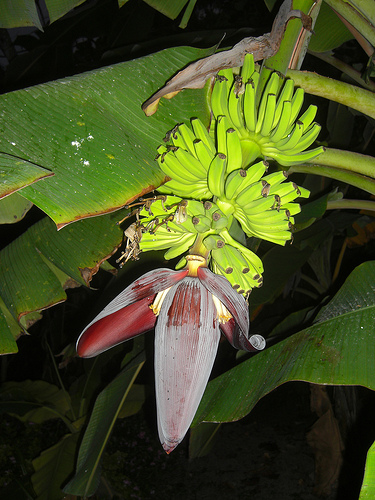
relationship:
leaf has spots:
[0, 34, 221, 235] [13, 117, 112, 178]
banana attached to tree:
[258, 93, 277, 138] [2, 1, 373, 499]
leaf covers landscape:
[0, 34, 221, 235] [2, 1, 373, 499]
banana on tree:
[258, 93, 277, 138] [2, 1, 373, 499]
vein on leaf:
[210, 298, 374, 393] [193, 255, 373, 426]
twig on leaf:
[123, 189, 168, 211] [0, 34, 221, 235]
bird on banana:
[141, 0, 314, 122] [258, 93, 277, 138]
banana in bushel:
[258, 93, 277, 138] [156, 116, 307, 248]